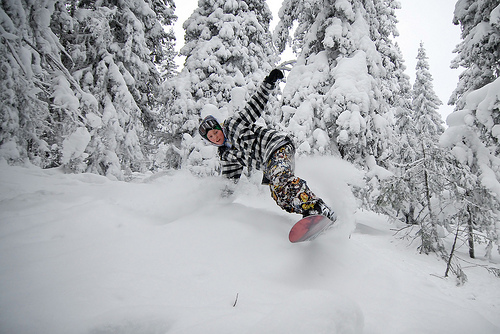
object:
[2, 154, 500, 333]
snow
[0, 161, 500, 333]
ground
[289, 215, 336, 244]
board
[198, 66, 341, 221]
woman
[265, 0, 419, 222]
trees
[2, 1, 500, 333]
snow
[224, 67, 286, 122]
arm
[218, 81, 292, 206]
jacket